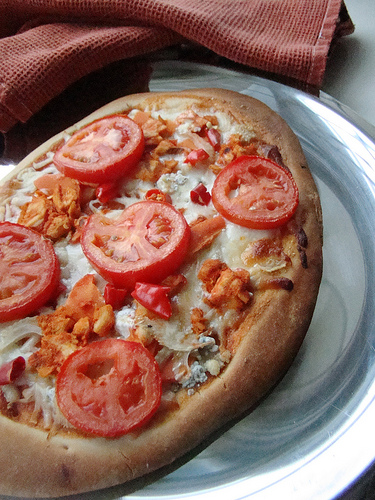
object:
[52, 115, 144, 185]
tomato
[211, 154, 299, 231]
slice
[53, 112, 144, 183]
slice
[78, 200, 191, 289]
slice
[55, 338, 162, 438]
slice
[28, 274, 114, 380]
meat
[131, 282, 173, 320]
pepper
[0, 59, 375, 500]
plate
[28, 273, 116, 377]
bacon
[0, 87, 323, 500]
crust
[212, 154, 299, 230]
tomato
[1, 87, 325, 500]
pizza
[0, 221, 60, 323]
slice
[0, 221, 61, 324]
tomato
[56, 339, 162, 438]
tomato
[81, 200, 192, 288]
tomato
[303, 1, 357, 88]
trim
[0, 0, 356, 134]
cloth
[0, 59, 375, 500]
silver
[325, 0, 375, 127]
gray table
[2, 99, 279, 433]
cheese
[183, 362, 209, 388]
blue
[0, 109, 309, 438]
toppings